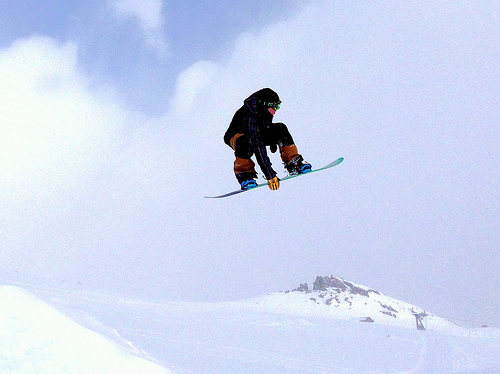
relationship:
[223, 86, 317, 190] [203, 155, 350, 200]
man on snowboard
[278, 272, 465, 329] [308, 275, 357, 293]
mountain has tip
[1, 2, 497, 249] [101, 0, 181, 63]
sky has clouds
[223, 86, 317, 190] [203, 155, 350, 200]
man has snowboard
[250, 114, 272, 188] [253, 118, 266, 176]
strip on arm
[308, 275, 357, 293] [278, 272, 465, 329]
tip of mountain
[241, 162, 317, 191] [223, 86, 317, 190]
boots on man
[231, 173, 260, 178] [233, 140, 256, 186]
socks on leg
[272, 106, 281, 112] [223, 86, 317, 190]
goggles on man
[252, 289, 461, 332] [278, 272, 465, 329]
snow on mountain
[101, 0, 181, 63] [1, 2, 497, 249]
clouds in sky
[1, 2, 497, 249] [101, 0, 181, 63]
sky in clouds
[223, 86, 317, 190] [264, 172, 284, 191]
man has hand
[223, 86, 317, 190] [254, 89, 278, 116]
man has head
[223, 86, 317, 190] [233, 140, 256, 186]
man has leg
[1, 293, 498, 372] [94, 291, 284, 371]
tracks in snow